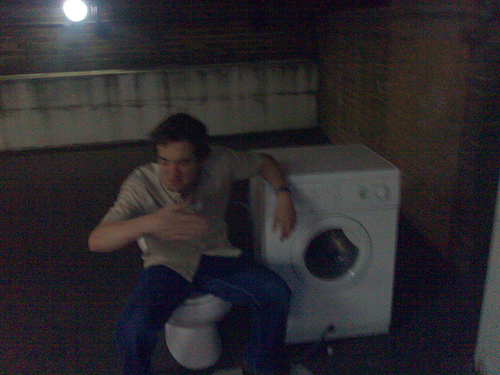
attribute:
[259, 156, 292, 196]
forearm — resting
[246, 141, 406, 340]
appliance — large, white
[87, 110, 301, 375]
man — sitting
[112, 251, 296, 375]
jeans — blue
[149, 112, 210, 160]
hair — dark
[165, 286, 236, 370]
toilet — white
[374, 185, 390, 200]
knob — white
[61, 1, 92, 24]
light — on, lit, bright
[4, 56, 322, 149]
wall — dirty, white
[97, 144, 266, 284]
shirt — tan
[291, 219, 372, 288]
door — round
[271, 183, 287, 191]
band — dark